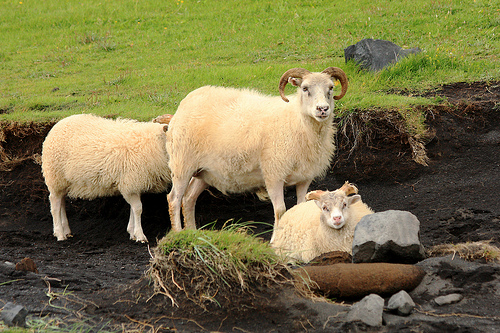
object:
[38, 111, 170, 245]
sheep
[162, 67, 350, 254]
sheep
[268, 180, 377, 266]
sheep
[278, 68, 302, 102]
horn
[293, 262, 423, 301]
log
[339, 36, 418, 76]
rock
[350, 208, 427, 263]
rock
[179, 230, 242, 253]
grass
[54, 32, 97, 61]
grass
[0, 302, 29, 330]
rock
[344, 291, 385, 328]
rock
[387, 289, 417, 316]
rock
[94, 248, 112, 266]
mud